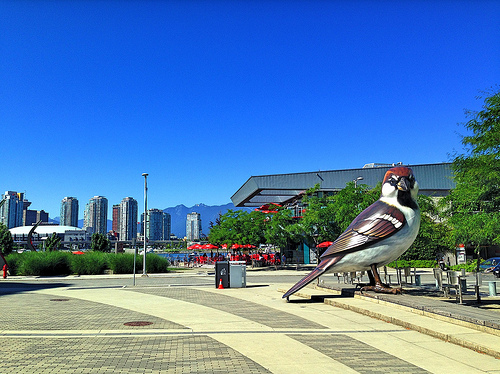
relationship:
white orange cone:
[219, 279, 225, 291] [218, 278, 226, 288]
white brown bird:
[219, 279, 225, 291] [284, 167, 417, 304]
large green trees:
[284, 167, 417, 304] [208, 97, 499, 293]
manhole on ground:
[123, 318, 150, 331] [126, 316, 152, 328]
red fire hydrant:
[0, 264, 9, 277] [1, 264, 7, 279]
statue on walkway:
[284, 167, 417, 304] [1, 257, 496, 371]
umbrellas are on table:
[181, 230, 268, 251] [189, 242, 278, 262]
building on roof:
[191, 147, 478, 271] [217, 157, 482, 188]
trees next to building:
[208, 97, 499, 293] [4, 172, 212, 252]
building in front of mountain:
[119, 196, 140, 248] [48, 204, 257, 236]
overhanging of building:
[232, 161, 500, 209] [233, 160, 497, 262]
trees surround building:
[208, 97, 499, 293] [233, 160, 497, 262]